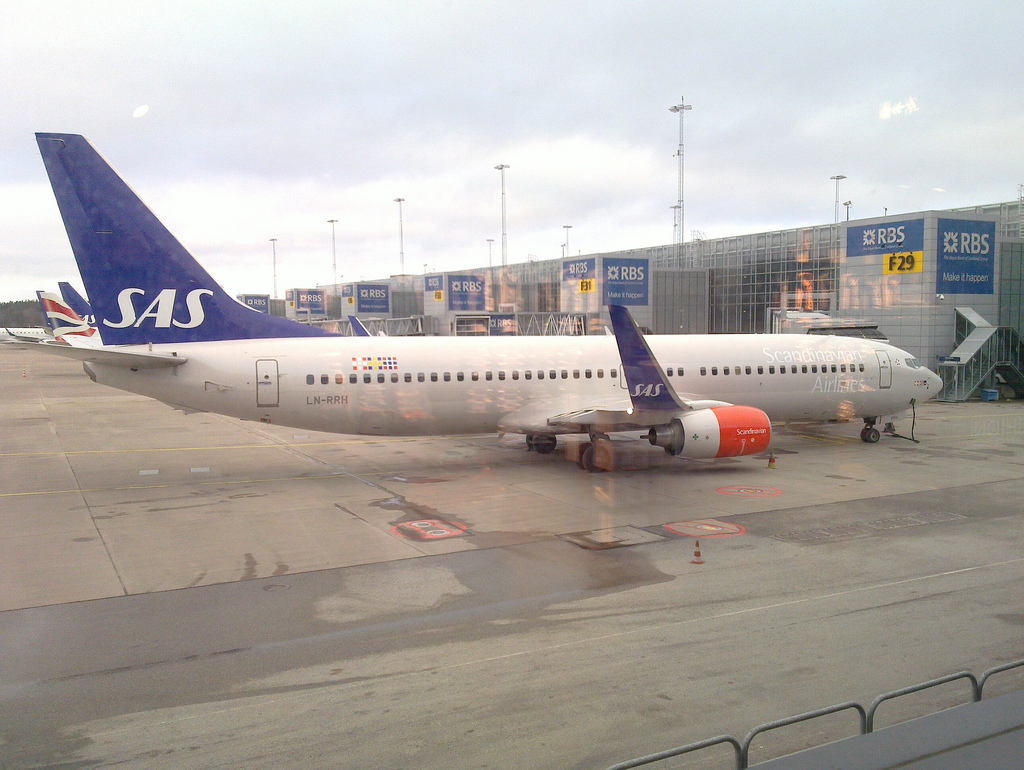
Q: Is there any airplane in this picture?
A: Yes, there is an airplane.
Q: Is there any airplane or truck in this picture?
A: Yes, there is an airplane.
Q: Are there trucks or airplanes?
A: Yes, there is an airplane.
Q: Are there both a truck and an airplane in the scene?
A: No, there is an airplane but no trucks.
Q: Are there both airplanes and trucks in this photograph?
A: No, there is an airplane but no trucks.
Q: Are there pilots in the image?
A: No, there are no pilots.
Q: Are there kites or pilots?
A: No, there are no pilots or kites.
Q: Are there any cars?
A: No, there are no cars.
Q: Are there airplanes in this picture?
A: Yes, there is an airplane.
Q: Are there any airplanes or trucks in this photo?
A: Yes, there is an airplane.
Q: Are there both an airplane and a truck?
A: No, there is an airplane but no trucks.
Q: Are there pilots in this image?
A: No, there are no pilots.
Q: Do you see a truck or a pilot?
A: No, there are no pilots or trucks.